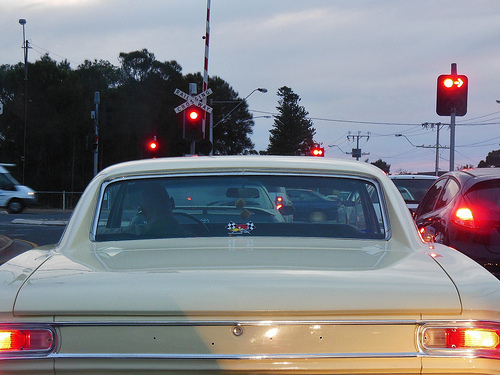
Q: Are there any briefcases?
A: No, there are no briefcases.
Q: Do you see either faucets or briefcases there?
A: No, there are no briefcases or faucets.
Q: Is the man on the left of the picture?
A: Yes, the man is on the left of the image.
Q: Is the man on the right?
A: No, the man is on the left of the image.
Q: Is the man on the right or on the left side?
A: The man is on the left of the image.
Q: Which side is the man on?
A: The man is on the left of the image.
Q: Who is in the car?
A: The man is in the car.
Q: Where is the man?
A: The man is in the car.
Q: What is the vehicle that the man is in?
A: The vehicle is a car.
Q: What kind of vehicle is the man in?
A: The man is in the car.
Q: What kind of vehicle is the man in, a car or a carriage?
A: The man is in a car.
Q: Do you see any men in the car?
A: Yes, there is a man in the car.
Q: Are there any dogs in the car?
A: No, there is a man in the car.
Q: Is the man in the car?
A: Yes, the man is in the car.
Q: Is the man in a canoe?
A: No, the man is in the car.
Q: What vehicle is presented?
A: The vehicle is a car.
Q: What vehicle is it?
A: The vehicle is a car.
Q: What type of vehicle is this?
A: This is a car.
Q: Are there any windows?
A: Yes, there is a window.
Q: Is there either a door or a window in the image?
A: Yes, there is a window.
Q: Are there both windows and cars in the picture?
A: Yes, there are both a window and a car.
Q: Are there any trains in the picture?
A: No, there are no trains.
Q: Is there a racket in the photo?
A: No, there are no rackets.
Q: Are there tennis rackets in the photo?
A: No, there are no tennis rackets.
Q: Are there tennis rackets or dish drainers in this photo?
A: No, there are no tennis rackets or dish drainers.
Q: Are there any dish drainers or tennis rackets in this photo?
A: No, there are no tennis rackets or dish drainers.